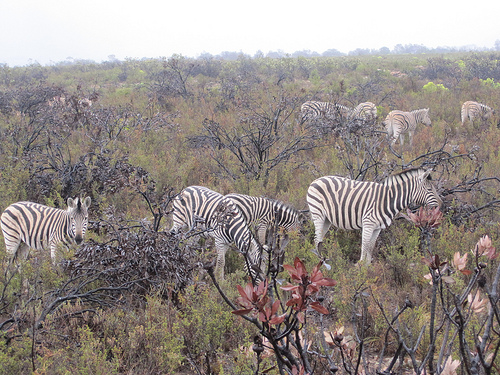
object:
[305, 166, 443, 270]
zebra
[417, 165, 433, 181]
ear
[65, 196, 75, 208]
ear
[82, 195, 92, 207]
ear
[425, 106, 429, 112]
ear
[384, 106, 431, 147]
zebra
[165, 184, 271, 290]
zebra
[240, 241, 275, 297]
head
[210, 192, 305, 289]
zebra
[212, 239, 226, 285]
leg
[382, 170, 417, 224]
zebra neck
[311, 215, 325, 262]
leg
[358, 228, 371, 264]
leg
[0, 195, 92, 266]
zebra